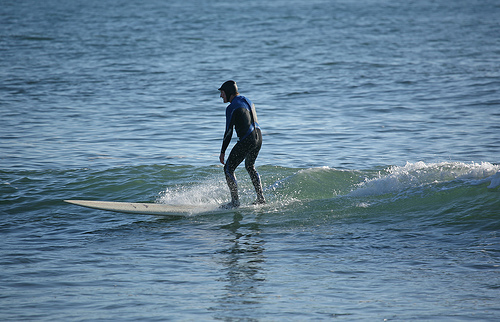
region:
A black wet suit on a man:
[213, 66, 273, 202]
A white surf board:
[60, 175, 281, 215]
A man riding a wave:
[201, 75, 391, 225]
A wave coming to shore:
[305, 135, 475, 215]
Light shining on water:
[265, 85, 365, 135]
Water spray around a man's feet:
[185, 170, 255, 210]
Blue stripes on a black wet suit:
[211, 85, 261, 155]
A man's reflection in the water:
[206, 205, 271, 310]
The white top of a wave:
[383, 154, 488, 178]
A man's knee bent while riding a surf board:
[210, 117, 265, 214]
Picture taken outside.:
[104, 30, 455, 64]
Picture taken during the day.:
[52, 17, 432, 81]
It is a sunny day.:
[40, 16, 440, 178]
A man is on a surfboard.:
[145, 87, 307, 275]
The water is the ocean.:
[97, 44, 197, 148]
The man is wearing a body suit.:
[175, 50, 322, 277]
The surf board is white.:
[75, 181, 206, 255]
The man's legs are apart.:
[202, 124, 289, 218]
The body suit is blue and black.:
[195, 60, 300, 231]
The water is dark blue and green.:
[47, 48, 152, 153]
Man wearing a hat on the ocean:
[216, 75, 243, 100]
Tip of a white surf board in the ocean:
[58, 191, 217, 225]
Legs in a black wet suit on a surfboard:
[214, 150, 269, 208]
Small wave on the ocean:
[273, 162, 492, 206]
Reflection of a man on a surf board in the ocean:
[206, 214, 273, 319]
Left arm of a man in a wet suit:
[213, 102, 228, 167]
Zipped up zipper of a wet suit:
[240, 97, 259, 139]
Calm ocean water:
[36, 12, 449, 75]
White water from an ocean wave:
[148, 177, 219, 203]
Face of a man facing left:
[211, 82, 228, 102]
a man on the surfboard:
[209, 77, 271, 206]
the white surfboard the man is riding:
[68, 195, 225, 215]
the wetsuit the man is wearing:
[221, 96, 262, 200]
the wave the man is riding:
[172, 165, 491, 215]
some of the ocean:
[17, 13, 209, 150]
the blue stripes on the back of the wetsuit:
[236, 99, 264, 136]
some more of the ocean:
[41, 227, 471, 319]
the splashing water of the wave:
[163, 177, 253, 205]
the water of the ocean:
[23, 28, 419, 147]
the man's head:
[216, 73, 241, 102]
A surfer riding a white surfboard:
[60, 70, 376, 228]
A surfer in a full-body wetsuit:
[197, 80, 282, 215]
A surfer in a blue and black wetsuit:
[190, 72, 280, 214]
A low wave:
[22, 154, 499, 216]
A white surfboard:
[63, 193, 298, 216]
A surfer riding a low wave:
[98, 57, 305, 217]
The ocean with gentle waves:
[8, 7, 485, 289]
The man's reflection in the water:
[194, 208, 278, 318]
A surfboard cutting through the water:
[64, 180, 304, 217]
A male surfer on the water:
[195, 68, 290, 222]